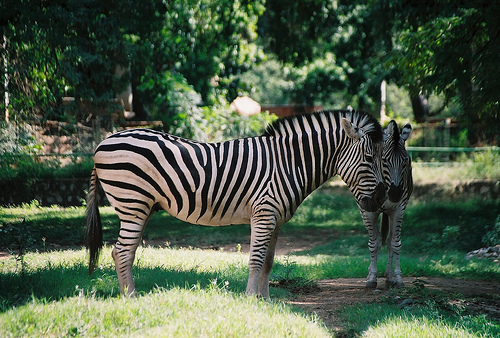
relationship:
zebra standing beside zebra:
[352, 116, 420, 297] [83, 109, 386, 301]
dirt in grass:
[306, 270, 490, 313] [2, 152, 496, 338]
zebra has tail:
[83, 109, 386, 301] [73, 159, 110, 279]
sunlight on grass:
[1, 249, 333, 336] [2, 152, 495, 336]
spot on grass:
[0, 276, 332, 336] [2, 152, 495, 336]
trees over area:
[1, 2, 497, 137] [10, 133, 496, 335]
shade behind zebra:
[1, 214, 499, 255] [83, 109, 386, 301]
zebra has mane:
[109, 91, 449, 321] [258, 105, 385, 148]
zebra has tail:
[83, 109, 386, 301] [80, 163, 104, 278]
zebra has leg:
[80, 108, 425, 302] [108, 199, 157, 313]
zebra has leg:
[83, 109, 386, 301] [246, 223, 287, 317]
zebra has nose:
[332, 91, 425, 287] [374, 196, 400, 218]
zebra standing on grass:
[83, 109, 386, 301] [2, 152, 495, 336]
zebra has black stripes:
[83, 109, 386, 301] [171, 126, 205, 205]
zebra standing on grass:
[360, 104, 421, 286] [2, 152, 495, 336]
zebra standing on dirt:
[352, 116, 420, 297] [307, 273, 493, 300]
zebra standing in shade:
[352, 116, 420, 297] [310, 256, 497, 329]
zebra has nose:
[83, 109, 386, 301] [372, 182, 385, 209]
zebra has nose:
[359, 118, 412, 291] [390, 183, 401, 201]